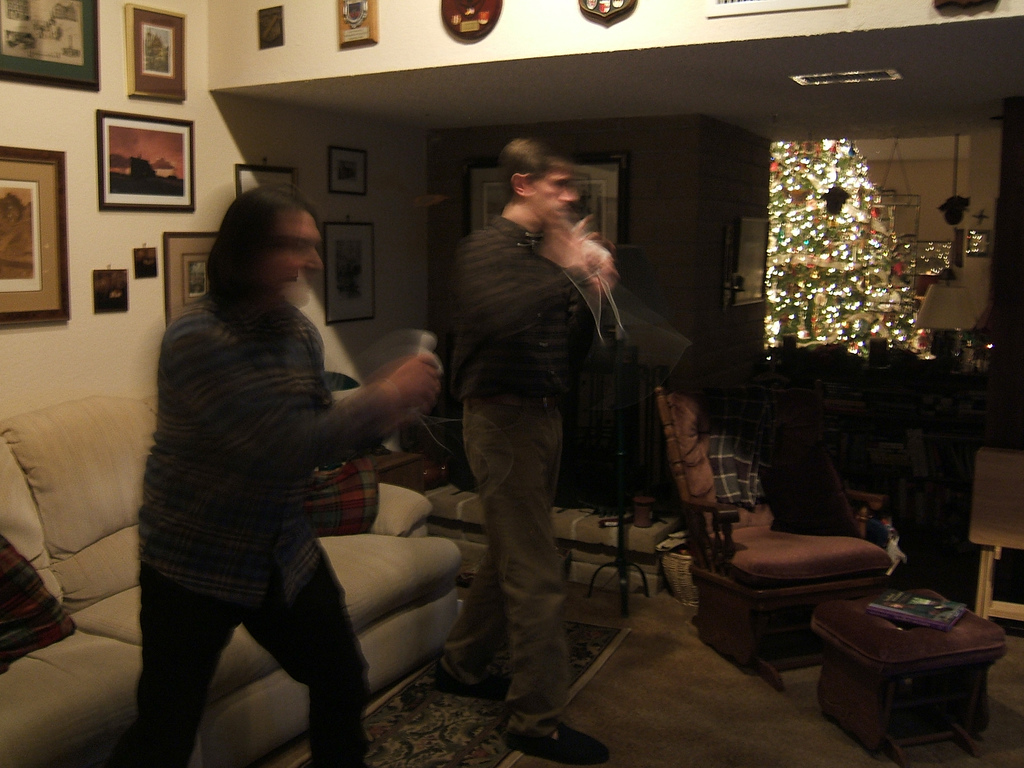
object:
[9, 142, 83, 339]
picture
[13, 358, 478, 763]
sofa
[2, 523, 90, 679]
pillow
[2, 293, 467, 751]
sofa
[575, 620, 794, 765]
rug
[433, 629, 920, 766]
floor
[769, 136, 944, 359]
lights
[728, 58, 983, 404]
wall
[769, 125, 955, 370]
christmas tree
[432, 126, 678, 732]
man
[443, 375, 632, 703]
pants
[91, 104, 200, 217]
picture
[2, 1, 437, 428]
wall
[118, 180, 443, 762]
man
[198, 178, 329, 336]
head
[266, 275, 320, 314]
chin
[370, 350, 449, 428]
hand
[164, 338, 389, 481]
arm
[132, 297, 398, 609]
shirt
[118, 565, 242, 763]
leg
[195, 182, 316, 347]
hair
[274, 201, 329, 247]
forehead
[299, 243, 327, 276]
nose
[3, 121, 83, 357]
picture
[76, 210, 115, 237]
wall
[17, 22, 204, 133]
picture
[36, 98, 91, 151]
wall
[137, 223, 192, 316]
picture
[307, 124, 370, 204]
picture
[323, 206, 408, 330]
picture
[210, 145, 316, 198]
picture